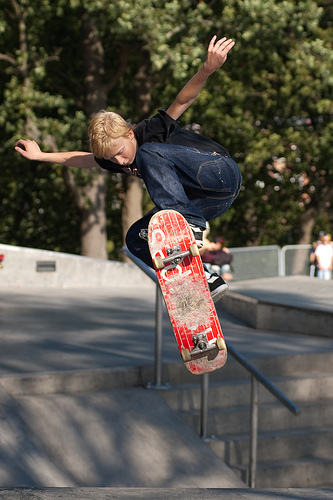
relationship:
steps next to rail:
[153, 353, 331, 487] [121, 244, 300, 495]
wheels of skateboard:
[211, 336, 225, 351] [145, 210, 233, 381]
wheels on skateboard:
[211, 336, 225, 351] [145, 210, 233, 381]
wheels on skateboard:
[179, 344, 194, 367] [145, 210, 233, 381]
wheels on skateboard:
[187, 239, 200, 257] [145, 210, 233, 381]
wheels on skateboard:
[154, 254, 164, 272] [145, 210, 233, 381]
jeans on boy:
[134, 134, 243, 225] [14, 34, 245, 302]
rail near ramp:
[121, 244, 300, 495] [1, 383, 255, 487]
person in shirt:
[311, 231, 332, 284] [314, 241, 332, 270]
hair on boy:
[89, 108, 132, 161] [14, 34, 245, 302]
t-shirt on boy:
[89, 104, 236, 185] [14, 34, 245, 302]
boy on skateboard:
[14, 34, 245, 302] [145, 210, 233, 381]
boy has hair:
[14, 34, 245, 302] [89, 108, 132, 161]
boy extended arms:
[14, 34, 245, 302] [149, 33, 237, 134]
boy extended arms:
[14, 34, 245, 302] [11, 135, 130, 176]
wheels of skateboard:
[187, 239, 200, 257] [145, 210, 233, 381]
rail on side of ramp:
[121, 244, 300, 495] [1, 383, 255, 487]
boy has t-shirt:
[14, 34, 245, 302] [89, 104, 236, 185]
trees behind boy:
[1, 0, 305, 264] [14, 34, 245, 302]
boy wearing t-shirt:
[14, 34, 245, 302] [89, 104, 236, 185]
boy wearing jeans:
[14, 34, 245, 302] [134, 134, 243, 225]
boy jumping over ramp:
[14, 34, 245, 302] [1, 383, 255, 487]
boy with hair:
[14, 34, 245, 302] [89, 108, 132, 161]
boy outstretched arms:
[14, 34, 245, 302] [149, 33, 237, 134]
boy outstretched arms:
[14, 34, 245, 302] [11, 135, 130, 176]